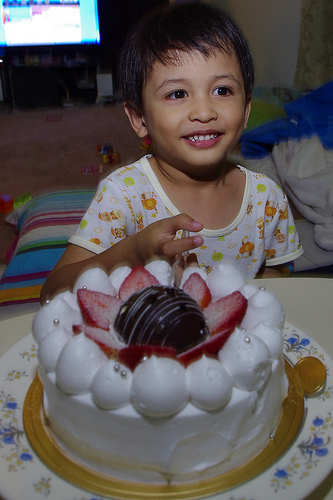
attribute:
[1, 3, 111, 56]
television — on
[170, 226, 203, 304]
knife — clear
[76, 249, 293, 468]
white cake — starberry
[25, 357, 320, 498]
plastic plate — faux, gold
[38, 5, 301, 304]
boy — little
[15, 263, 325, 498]
cake tray — yellow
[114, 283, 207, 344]
ball — Large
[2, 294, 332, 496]
plate — white floral 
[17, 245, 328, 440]
cake — fluffy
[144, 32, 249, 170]
child — smiling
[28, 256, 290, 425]
puffs — White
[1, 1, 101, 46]
television — bright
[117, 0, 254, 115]
hair — brown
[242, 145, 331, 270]
linens — assorted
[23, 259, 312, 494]
cake — birthday cake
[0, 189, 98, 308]
pillow — multi colored, multi-colored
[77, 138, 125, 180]
toys — child's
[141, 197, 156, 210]
design — orange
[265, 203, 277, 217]
design — orange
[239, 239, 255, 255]
design — orange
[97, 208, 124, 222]
design — orange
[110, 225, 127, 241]
design — orange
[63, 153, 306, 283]
t-shirt — small, white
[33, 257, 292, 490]
cake — silver, white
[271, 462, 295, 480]
flower — blue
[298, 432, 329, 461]
flower — blue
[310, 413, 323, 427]
flower — blue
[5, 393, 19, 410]
flower — blue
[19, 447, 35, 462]
flower — blue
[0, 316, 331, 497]
plate — round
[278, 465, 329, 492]
tray — yellow cake 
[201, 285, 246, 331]
strawberry — large, cut in half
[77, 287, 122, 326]
strawberry — large, cut in half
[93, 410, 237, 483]
icing —  vanilla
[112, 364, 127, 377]
beads —  small ,  grey,  on top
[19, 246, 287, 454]
cake — white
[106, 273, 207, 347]
candy — chocolate, sphere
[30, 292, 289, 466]
frosting — white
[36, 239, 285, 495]
cake — white